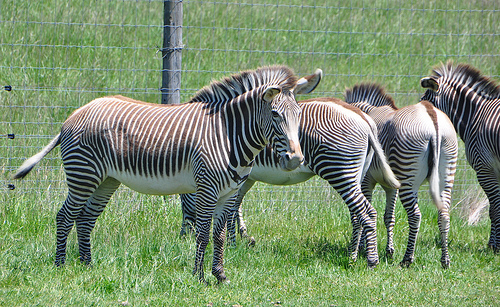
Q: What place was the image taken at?
A: It was taken at the field.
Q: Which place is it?
A: It is a field.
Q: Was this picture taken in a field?
A: Yes, it was taken in a field.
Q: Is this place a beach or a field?
A: It is a field.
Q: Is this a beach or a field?
A: It is a field.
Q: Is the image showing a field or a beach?
A: It is showing a field.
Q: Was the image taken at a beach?
A: No, the picture was taken in a field.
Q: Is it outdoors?
A: Yes, it is outdoors.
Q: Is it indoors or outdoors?
A: It is outdoors.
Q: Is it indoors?
A: No, it is outdoors.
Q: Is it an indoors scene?
A: No, it is outdoors.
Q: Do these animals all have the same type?
A: Yes, all the animals are zebras.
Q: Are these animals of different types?
A: No, all the animals are zebras.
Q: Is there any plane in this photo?
A: No, there are no airplanes.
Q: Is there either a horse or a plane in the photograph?
A: No, there are no airplanes or horses.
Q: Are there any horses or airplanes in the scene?
A: No, there are no airplanes or horses.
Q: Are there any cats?
A: No, there are no cats.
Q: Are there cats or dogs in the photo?
A: No, there are no cats or dogs.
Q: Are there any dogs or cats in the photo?
A: No, there are no cats or dogs.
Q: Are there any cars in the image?
A: No, there are no cars.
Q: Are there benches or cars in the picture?
A: No, there are no cars or benches.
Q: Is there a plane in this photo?
A: No, there are no airplanes.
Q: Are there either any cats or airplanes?
A: No, there are no airplanes or cats.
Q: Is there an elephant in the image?
A: No, there are no elephants.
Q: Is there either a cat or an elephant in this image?
A: No, there are no elephants or cats.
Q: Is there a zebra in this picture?
A: Yes, there is a zebra.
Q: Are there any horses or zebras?
A: Yes, there is a zebra.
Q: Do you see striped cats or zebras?
A: Yes, there is a striped zebra.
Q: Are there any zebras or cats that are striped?
A: Yes, the zebra is striped.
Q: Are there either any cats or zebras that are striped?
A: Yes, the zebra is striped.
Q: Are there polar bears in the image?
A: No, there are no polar bears.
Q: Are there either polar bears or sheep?
A: No, there are no polar bears or sheep.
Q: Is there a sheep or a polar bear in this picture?
A: No, there are no polar bears or sheep.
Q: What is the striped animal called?
A: The animal is a zebra.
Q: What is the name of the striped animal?
A: The animal is a zebra.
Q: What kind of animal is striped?
A: The animal is a zebra.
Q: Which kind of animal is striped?
A: The animal is a zebra.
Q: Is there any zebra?
A: Yes, there is a zebra.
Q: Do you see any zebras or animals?
A: Yes, there is a zebra.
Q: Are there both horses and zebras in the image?
A: No, there is a zebra but no horses.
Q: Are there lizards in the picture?
A: No, there are no lizards.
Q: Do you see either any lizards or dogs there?
A: No, there are no lizards or dogs.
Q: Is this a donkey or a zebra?
A: This is a zebra.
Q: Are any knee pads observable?
A: No, there are no knee pads.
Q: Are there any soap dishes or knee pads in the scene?
A: No, there are no knee pads or soap dishes.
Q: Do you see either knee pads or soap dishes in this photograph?
A: No, there are no knee pads or soap dishes.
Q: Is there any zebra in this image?
A: Yes, there is a zebra.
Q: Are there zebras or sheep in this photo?
A: Yes, there is a zebra.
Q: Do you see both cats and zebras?
A: No, there is a zebra but no cats.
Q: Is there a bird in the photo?
A: No, there are no birds.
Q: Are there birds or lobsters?
A: No, there are no birds or lobsters.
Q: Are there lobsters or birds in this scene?
A: No, there are no birds or lobsters.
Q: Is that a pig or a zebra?
A: That is a zebra.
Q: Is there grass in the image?
A: Yes, there is grass.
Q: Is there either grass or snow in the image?
A: Yes, there is grass.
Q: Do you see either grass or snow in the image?
A: Yes, there is grass.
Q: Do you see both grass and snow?
A: No, there is grass but no snow.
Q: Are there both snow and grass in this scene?
A: No, there is grass but no snow.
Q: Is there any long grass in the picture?
A: Yes, there is long grass.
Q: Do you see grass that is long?
A: Yes, there is grass that is long.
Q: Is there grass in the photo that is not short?
A: Yes, there is long grass.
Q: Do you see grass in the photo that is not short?
A: Yes, there is long grass.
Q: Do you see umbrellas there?
A: No, there are no umbrellas.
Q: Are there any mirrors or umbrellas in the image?
A: No, there are no umbrellas or mirrors.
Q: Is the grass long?
A: Yes, the grass is long.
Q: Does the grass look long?
A: Yes, the grass is long.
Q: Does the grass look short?
A: No, the grass is long.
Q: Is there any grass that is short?
A: No, there is grass but it is long.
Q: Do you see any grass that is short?
A: No, there is grass but it is long.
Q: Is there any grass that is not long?
A: No, there is grass but it is long.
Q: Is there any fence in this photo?
A: Yes, there is a fence.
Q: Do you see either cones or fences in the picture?
A: Yes, there is a fence.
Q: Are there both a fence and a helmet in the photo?
A: No, there is a fence but no helmets.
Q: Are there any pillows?
A: No, there are no pillows.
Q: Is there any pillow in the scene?
A: No, there are no pillows.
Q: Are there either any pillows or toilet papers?
A: No, there are no pillows or toilet papers.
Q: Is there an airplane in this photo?
A: No, there are no airplanes.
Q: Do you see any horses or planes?
A: No, there are no planes or horses.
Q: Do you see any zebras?
A: Yes, there is a zebra.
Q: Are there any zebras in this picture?
A: Yes, there is a zebra.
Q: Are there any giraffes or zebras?
A: Yes, there is a zebra.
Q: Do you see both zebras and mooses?
A: No, there is a zebra but no mooses.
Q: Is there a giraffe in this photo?
A: No, there are no giraffes.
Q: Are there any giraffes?
A: No, there are no giraffes.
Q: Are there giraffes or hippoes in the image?
A: No, there are no giraffes or hippoes.